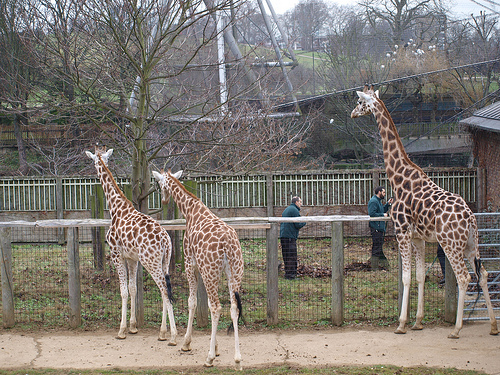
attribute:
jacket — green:
[278, 205, 306, 237]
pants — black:
[279, 234, 300, 280]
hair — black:
[373, 186, 383, 195]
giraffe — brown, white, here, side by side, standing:
[348, 85, 499, 338]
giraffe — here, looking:
[83, 142, 177, 348]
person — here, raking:
[280, 195, 309, 278]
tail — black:
[232, 289, 246, 324]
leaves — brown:
[303, 262, 327, 276]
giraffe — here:
[153, 168, 245, 372]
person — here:
[366, 189, 392, 262]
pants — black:
[368, 221, 389, 269]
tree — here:
[2, 1, 329, 261]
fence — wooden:
[240, 207, 405, 313]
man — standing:
[278, 192, 307, 276]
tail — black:
[161, 267, 176, 302]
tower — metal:
[121, 3, 306, 120]